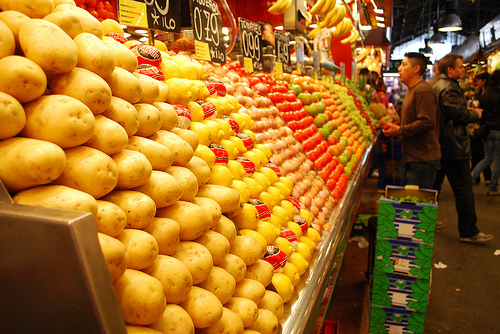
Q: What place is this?
A: It is a store.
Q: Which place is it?
A: It is a store.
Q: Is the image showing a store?
A: Yes, it is showing a store.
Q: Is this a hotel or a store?
A: It is a store.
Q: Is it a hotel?
A: No, it is a store.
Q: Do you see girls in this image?
A: No, there are no girls.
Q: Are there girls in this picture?
A: No, there are no girls.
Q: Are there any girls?
A: No, there are no girls.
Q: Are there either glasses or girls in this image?
A: No, there are no girls or glasses.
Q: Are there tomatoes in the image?
A: Yes, there are tomatoes.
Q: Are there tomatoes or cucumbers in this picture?
A: Yes, there are tomatoes.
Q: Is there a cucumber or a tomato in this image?
A: Yes, there are tomatoes.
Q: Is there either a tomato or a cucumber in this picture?
A: Yes, there are tomatoes.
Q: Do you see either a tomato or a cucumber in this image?
A: Yes, there are tomatoes.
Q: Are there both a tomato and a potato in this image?
A: Yes, there are both a tomato and a potato.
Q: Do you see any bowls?
A: No, there are no bowls.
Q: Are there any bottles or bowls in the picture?
A: No, there are no bowls or bottles.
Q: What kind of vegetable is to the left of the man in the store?
A: The vegetables are tomatoes.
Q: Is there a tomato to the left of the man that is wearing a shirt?
A: Yes, there are tomatoes to the left of the man.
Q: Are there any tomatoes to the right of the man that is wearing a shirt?
A: No, the tomatoes are to the left of the man.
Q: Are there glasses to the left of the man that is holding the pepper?
A: No, there are tomatoes to the left of the man.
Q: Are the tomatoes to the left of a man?
A: Yes, the tomatoes are to the left of a man.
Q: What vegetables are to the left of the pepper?
A: The vegetables are tomatoes.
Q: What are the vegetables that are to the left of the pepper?
A: The vegetables are tomatoes.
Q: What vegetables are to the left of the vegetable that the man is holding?
A: The vegetables are tomatoes.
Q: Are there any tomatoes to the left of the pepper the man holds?
A: Yes, there are tomatoes to the left of the pepper.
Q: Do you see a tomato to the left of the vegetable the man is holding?
A: Yes, there are tomatoes to the left of the pepper.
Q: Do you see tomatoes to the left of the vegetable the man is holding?
A: Yes, there are tomatoes to the left of the pepper.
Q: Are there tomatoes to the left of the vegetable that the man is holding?
A: Yes, there are tomatoes to the left of the pepper.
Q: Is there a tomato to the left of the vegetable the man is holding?
A: Yes, there are tomatoes to the left of the pepper.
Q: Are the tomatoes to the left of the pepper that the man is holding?
A: Yes, the tomatoes are to the left of the pepper.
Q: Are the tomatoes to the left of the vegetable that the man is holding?
A: Yes, the tomatoes are to the left of the pepper.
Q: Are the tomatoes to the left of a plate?
A: No, the tomatoes are to the left of the pepper.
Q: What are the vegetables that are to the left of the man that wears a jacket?
A: The vegetables are tomatoes.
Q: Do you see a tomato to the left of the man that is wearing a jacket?
A: Yes, there are tomatoes to the left of the man.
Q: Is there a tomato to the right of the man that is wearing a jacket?
A: No, the tomatoes are to the left of the man.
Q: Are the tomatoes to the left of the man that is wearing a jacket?
A: Yes, the tomatoes are to the left of the man.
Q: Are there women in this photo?
A: No, there are no women.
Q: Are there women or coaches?
A: No, there are no women or coaches.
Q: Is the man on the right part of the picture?
A: Yes, the man is on the right of the image.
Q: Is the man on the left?
A: No, the man is on the right of the image.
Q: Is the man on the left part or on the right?
A: The man is on the right of the image.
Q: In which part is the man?
A: The man is on the right of the image.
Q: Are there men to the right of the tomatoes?
A: Yes, there is a man to the right of the tomatoes.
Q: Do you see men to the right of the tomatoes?
A: Yes, there is a man to the right of the tomatoes.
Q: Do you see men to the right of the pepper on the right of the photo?
A: Yes, there is a man to the right of the pepper.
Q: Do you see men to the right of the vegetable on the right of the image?
A: Yes, there is a man to the right of the pepper.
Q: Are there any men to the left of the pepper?
A: No, the man is to the right of the pepper.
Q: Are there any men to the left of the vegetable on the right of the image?
A: No, the man is to the right of the pepper.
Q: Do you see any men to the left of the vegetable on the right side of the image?
A: No, the man is to the right of the pepper.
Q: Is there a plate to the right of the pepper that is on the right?
A: No, there is a man to the right of the pepper.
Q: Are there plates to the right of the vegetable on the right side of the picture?
A: No, there is a man to the right of the pepper.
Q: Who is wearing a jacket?
A: The man is wearing a jacket.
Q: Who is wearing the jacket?
A: The man is wearing a jacket.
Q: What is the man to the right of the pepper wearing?
A: The man is wearing a jacket.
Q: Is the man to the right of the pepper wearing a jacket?
A: Yes, the man is wearing a jacket.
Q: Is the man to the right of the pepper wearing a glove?
A: No, the man is wearing a jacket.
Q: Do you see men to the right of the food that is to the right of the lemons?
A: Yes, there is a man to the right of the food.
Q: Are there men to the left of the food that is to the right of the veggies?
A: No, the man is to the right of the food.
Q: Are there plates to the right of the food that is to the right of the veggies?
A: No, there is a man to the right of the food.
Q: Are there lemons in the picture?
A: Yes, there are lemons.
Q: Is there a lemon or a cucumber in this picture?
A: Yes, there are lemons.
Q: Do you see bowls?
A: No, there are no bowls.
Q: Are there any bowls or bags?
A: No, there are no bowls or bags.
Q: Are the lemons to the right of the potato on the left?
A: Yes, the lemons are to the right of the potato.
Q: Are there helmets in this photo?
A: No, there are no helmets.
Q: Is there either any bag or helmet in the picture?
A: No, there are no helmets or bags.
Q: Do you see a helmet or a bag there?
A: No, there are no helmets or bags.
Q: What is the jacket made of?
A: The jacket is made of leather.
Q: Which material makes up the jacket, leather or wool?
A: The jacket is made of leather.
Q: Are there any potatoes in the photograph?
A: Yes, there is a potato.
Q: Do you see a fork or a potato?
A: Yes, there is a potato.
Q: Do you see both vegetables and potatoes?
A: Yes, there are both a potato and vegetables.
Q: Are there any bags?
A: No, there are no bags.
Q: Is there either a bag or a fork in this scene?
A: No, there are no bags or forks.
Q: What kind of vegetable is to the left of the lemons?
A: The vegetable is a potato.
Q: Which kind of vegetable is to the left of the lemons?
A: The vegetable is a potato.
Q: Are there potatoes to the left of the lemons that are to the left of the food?
A: Yes, there is a potato to the left of the lemons.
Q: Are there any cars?
A: No, there are no cars.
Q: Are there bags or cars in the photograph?
A: No, there are no cars or bags.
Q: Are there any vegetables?
A: Yes, there are vegetables.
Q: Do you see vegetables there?
A: Yes, there are vegetables.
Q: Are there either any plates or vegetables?
A: Yes, there are vegetables.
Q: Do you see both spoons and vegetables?
A: No, there are vegetables but no spoons.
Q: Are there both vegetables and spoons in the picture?
A: No, there are vegetables but no spoons.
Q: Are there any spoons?
A: No, there are no spoons.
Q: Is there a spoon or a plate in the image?
A: No, there are no spoons or plates.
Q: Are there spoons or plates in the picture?
A: No, there are no spoons or plates.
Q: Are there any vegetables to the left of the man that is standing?
A: Yes, there are vegetables to the left of the man.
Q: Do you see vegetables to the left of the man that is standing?
A: Yes, there are vegetables to the left of the man.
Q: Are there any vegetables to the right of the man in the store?
A: No, the vegetables are to the left of the man.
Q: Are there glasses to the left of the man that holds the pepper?
A: No, there are vegetables to the left of the man.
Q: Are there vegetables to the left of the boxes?
A: Yes, there are vegetables to the left of the boxes.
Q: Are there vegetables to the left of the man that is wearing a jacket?
A: Yes, there are vegetables to the left of the man.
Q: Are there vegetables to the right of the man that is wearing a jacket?
A: No, the vegetables are to the left of the man.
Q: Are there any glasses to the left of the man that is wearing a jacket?
A: No, there are vegetables to the left of the man.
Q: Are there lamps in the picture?
A: Yes, there is a lamp.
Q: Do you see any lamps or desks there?
A: Yes, there is a lamp.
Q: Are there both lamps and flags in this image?
A: No, there is a lamp but no flags.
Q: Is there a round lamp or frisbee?
A: Yes, there is a round lamp.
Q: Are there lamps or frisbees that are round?
A: Yes, the lamp is round.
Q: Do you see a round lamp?
A: Yes, there is a round lamp.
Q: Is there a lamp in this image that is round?
A: Yes, there is a lamp that is round.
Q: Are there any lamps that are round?
A: Yes, there is a lamp that is round.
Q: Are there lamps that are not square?
A: Yes, there is a round lamp.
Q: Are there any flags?
A: No, there are no flags.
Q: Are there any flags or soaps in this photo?
A: No, there are no flags or soaps.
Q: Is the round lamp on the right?
A: Yes, the lamp is on the right of the image.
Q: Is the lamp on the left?
A: No, the lamp is on the right of the image.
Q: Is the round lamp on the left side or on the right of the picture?
A: The lamp is on the right of the image.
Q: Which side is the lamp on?
A: The lamp is on the right of the image.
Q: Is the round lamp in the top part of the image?
A: Yes, the lamp is in the top of the image.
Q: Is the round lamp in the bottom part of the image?
A: No, the lamp is in the top of the image.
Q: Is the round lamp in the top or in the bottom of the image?
A: The lamp is in the top of the image.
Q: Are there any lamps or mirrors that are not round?
A: No, there is a lamp but it is round.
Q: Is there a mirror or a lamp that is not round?
A: No, there is a lamp but it is round.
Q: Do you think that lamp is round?
A: Yes, the lamp is round.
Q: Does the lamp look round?
A: Yes, the lamp is round.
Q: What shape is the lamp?
A: The lamp is round.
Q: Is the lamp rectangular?
A: No, the lamp is round.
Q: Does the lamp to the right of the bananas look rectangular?
A: No, the lamp is round.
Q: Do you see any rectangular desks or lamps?
A: No, there is a lamp but it is round.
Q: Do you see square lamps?
A: No, there is a lamp but it is round.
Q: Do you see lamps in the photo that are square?
A: No, there is a lamp but it is round.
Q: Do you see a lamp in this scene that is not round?
A: No, there is a lamp but it is round.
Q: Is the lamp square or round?
A: The lamp is round.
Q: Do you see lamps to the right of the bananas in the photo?
A: Yes, there is a lamp to the right of the bananas.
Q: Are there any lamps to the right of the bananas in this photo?
A: Yes, there is a lamp to the right of the bananas.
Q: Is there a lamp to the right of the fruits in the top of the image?
A: Yes, there is a lamp to the right of the bananas.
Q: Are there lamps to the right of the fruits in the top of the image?
A: Yes, there is a lamp to the right of the bananas.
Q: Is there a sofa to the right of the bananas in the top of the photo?
A: No, there is a lamp to the right of the bananas.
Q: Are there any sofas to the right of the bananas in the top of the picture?
A: No, there is a lamp to the right of the bananas.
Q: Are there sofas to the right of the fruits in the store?
A: No, there is a lamp to the right of the bananas.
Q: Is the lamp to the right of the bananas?
A: Yes, the lamp is to the right of the bananas.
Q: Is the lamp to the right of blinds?
A: No, the lamp is to the right of the bananas.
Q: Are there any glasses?
A: No, there are no glasses.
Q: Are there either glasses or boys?
A: No, there are no glasses or boys.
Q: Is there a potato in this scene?
A: Yes, there are potatoes.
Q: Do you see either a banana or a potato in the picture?
A: Yes, there are potatoes.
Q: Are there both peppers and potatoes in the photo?
A: Yes, there are both potatoes and a pepper.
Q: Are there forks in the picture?
A: No, there are no forks.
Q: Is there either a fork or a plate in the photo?
A: No, there are no forks or plates.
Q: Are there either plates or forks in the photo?
A: No, there are no forks or plates.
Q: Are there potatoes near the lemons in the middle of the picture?
A: Yes, there are potatoes near the lemons.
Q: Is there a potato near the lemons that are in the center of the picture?
A: Yes, there are potatoes near the lemons.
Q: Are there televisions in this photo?
A: No, there are no televisions.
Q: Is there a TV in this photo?
A: No, there are no televisions.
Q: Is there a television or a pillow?
A: No, there are no televisions or pillows.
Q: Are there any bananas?
A: Yes, there are bananas.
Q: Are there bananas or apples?
A: Yes, there are bananas.